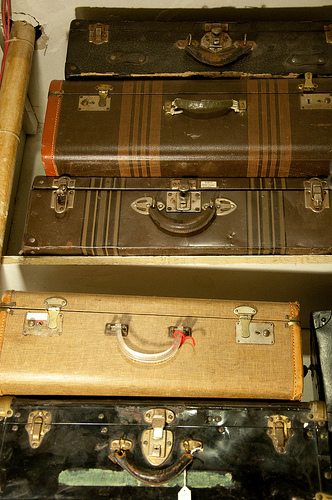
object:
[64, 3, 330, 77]
suitcases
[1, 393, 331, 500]
suitcase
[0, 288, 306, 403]
suitcase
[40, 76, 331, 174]
suitcase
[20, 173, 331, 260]
suitcase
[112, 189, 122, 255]
stripes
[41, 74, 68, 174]
side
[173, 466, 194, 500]
tag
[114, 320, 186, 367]
handle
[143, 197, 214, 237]
handle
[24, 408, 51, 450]
clasp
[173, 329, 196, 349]
ribbon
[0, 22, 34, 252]
pipe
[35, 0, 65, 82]
wall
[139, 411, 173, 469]
latch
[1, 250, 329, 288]
wall